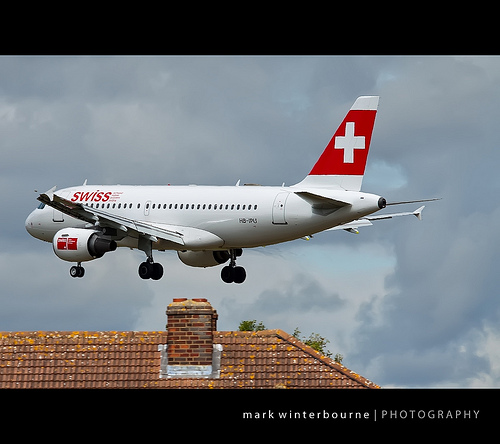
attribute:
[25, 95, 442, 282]
plane — flying low, swiss airlines, swiss, in sky, gray, flying away, red, white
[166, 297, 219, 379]
chimney — brick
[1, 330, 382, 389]
roof — red brick, brown, orange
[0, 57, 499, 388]
clouds — on side, big, grey, in sky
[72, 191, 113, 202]
logo — swiss airlines, in corner, airline name, red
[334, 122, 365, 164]
cross — gray, on back, white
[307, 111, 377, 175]
part — red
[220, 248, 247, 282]
gear — for landing, down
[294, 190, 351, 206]
wing — with red on it, back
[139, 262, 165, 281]
wheels — black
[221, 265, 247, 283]
wheels — black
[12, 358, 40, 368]
tile — red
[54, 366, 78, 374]
tile — red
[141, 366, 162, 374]
tile — red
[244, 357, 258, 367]
tile — red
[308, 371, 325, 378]
tile — red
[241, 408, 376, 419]
logo — mark winterbourne, mark winterbourn